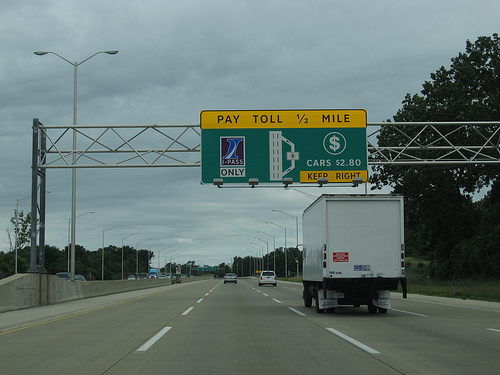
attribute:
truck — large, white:
[297, 190, 409, 313]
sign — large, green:
[204, 111, 359, 183]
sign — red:
[329, 247, 352, 264]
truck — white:
[258, 157, 452, 357]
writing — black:
[252, 110, 284, 124]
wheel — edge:
[309, 287, 339, 305]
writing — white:
[304, 154, 362, 173]